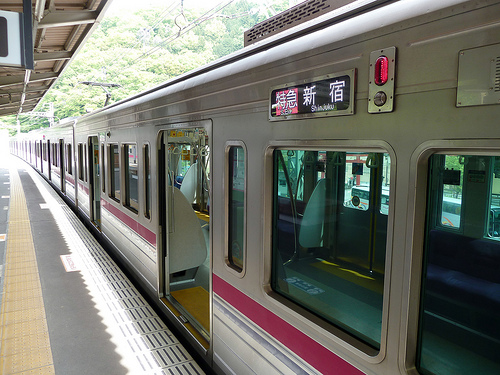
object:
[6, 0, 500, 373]
train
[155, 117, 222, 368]
door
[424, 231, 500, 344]
seats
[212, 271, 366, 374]
line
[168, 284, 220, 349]
doorway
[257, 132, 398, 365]
windows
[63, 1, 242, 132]
wires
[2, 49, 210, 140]
trees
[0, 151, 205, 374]
floor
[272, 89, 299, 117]
characters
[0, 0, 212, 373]
station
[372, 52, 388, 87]
light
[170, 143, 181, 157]
hanger straps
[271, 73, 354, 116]
sign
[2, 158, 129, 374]
shadow